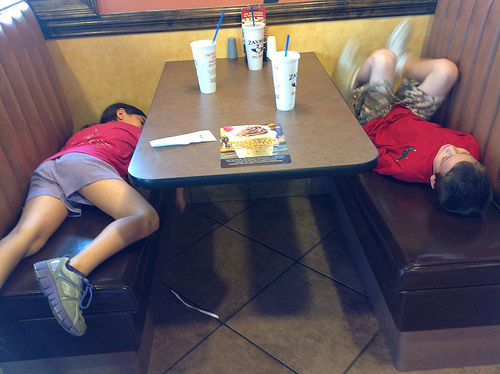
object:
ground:
[144, 179, 401, 373]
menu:
[220, 120, 292, 168]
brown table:
[128, 51, 380, 188]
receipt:
[150, 129, 217, 149]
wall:
[40, 7, 439, 205]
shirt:
[34, 121, 142, 180]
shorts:
[23, 149, 127, 219]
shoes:
[387, 15, 418, 75]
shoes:
[333, 36, 360, 95]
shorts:
[349, 75, 445, 125]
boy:
[333, 16, 492, 222]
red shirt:
[363, 105, 480, 185]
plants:
[189, 6, 300, 112]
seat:
[0, 0, 159, 373]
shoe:
[31, 256, 96, 337]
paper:
[169, 288, 220, 321]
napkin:
[150, 129, 218, 149]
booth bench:
[337, 0, 499, 372]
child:
[0, 101, 164, 337]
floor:
[142, 184, 500, 373]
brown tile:
[164, 224, 296, 320]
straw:
[284, 34, 290, 57]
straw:
[250, 7, 255, 26]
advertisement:
[218, 121, 292, 168]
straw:
[211, 12, 225, 45]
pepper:
[227, 37, 238, 60]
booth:
[0, 0, 499, 374]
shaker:
[226, 36, 238, 60]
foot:
[331, 37, 363, 96]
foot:
[386, 16, 416, 73]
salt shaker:
[266, 36, 278, 58]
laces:
[76, 275, 93, 310]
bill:
[149, 129, 218, 148]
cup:
[241, 20, 265, 70]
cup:
[270, 50, 301, 111]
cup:
[190, 40, 218, 94]